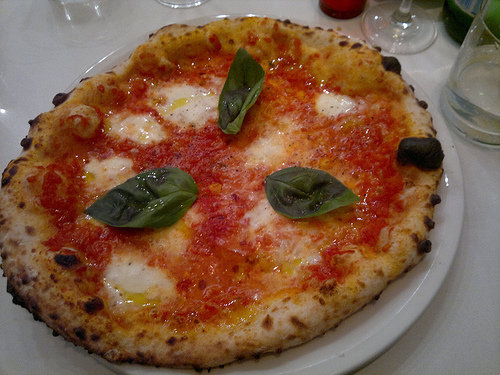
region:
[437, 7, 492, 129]
empty drinking glass on the table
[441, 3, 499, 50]
green glass bottle on the table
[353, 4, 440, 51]
stem and base of wineglass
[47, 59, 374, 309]
blobs of cheese on the pizza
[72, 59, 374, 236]
leaves laid on the pizza toppings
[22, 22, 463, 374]
white plate the pizza is placed on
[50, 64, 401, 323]
red sauce on the pizza crust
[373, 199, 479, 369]
shadows on the tablecloth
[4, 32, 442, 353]
burnt spots on the pizza crust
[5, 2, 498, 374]
white tablecloth plate is on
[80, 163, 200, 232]
Greasy spinach leaf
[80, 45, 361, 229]
Three spinach leaves on a pizza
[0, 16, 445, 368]
Small welldone baked pizza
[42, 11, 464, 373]
Round white dinner plate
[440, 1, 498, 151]
Short glass of water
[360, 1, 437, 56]
Glass base of a wine glass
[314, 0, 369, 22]
Bottom of a red cup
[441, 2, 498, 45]
Green glass bottle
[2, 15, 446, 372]
Pizza with sauce, cheese and spinach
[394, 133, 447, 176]
Burnt pizza crust bubble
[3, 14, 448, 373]
pizza on white plate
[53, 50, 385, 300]
sauce on the pizza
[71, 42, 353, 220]
green leaves on the pizza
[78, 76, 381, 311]
cheese on the pizza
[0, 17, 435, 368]
crust of the pizza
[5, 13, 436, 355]
burnt spots on the pizza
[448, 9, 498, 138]
drinking glass on the table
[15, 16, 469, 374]
white plate the pizza is on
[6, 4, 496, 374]
white tablecloth on the table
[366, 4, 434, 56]
base of a wine glass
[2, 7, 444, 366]
pizza on a plate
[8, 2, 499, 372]
white plate on white tablecloth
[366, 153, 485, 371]
shadow of the plate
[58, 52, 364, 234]
leaves topping the pizza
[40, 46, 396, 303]
red sauce on the pizza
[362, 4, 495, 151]
drinking glasses on the table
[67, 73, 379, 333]
yellow grease on the pizza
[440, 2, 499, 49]
green bottle on the table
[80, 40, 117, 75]
glare of light on the plate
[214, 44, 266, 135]
basil leaf on pizza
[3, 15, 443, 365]
small cheese pizza with basil leaves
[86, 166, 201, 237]
basil leaf on pizza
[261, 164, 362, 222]
basil leaf on pizza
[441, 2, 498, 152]
glass of water on white surface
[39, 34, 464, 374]
white plate containing pizza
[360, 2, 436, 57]
base of a glass wineglass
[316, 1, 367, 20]
base of a red container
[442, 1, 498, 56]
base of a green container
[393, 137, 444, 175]
burnt bubble on pizza crust